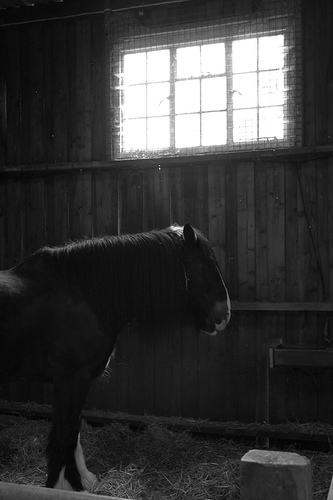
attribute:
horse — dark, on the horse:
[0, 218, 234, 494]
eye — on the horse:
[191, 258, 205, 273]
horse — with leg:
[26, 196, 230, 465]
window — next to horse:
[95, 11, 294, 160]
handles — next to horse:
[156, 87, 243, 107]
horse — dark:
[0, 217, 229, 403]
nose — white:
[208, 304, 227, 332]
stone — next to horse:
[223, 441, 312, 490]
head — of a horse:
[115, 195, 258, 333]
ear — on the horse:
[181, 221, 199, 245]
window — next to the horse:
[109, 14, 297, 162]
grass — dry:
[118, 449, 201, 498]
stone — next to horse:
[236, 444, 316, 499]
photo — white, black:
[6, 16, 329, 387]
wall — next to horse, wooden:
[0, 0, 331, 448]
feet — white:
[45, 458, 98, 490]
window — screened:
[104, 0, 303, 163]